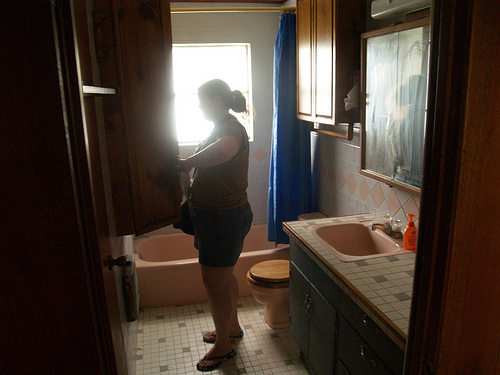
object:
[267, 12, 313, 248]
curtain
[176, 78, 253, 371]
lady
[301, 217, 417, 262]
sink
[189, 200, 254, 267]
shorts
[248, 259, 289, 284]
toilet cover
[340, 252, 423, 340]
counter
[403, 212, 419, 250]
bottle